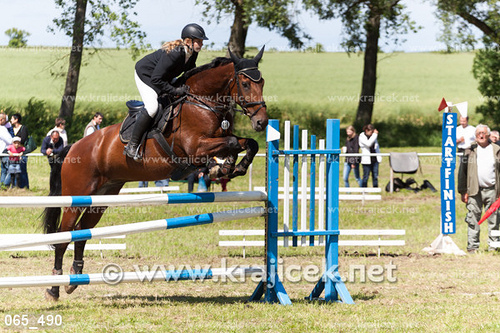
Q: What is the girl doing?
A: Horseback riding.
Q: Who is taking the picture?
A: A photographer.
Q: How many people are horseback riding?
A: 1 person riding.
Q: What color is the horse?
A: The horse is brown.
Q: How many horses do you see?
A: 1 horse.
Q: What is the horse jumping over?
A: The horse is jumping over bars.